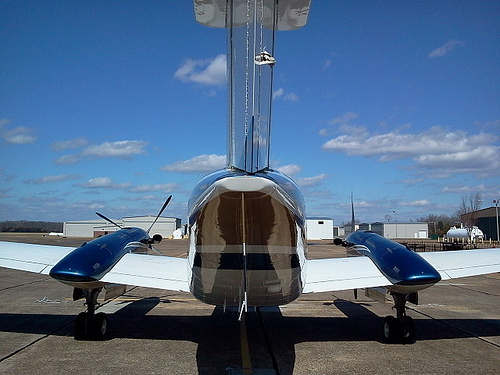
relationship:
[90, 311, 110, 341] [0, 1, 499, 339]
wheel on jet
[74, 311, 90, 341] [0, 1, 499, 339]
wheel on jet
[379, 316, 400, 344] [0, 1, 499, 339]
wheel on jet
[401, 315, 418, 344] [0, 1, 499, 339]
wheel on jet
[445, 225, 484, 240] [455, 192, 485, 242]
tank behind tree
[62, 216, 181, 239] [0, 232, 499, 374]
building on top of tarmac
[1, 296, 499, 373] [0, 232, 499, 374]
shadow on top of ground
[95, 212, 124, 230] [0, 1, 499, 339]
propeller on plane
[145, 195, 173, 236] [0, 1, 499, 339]
propeller on plane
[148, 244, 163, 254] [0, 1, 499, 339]
propeller on plane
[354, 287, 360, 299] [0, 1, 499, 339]
propeller on plane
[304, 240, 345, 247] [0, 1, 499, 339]
propeller on plane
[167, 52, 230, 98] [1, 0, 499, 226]
cloud in sky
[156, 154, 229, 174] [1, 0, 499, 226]
cloud in sky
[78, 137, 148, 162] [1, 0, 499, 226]
cloud in sky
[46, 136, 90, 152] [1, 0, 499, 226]
cloud in sky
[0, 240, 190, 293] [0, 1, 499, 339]
wing of plane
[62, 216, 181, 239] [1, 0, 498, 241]
building in background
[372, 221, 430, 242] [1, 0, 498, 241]
building in background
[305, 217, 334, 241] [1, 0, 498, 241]
building in background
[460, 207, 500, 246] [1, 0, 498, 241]
building in background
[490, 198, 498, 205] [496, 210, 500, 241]
street light on top of pole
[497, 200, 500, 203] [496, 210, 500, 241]
street light on top of pole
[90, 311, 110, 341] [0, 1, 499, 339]
wheel of jet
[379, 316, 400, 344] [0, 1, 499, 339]
wheel of jet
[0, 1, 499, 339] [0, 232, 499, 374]
jet on top of tarmac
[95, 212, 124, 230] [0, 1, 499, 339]
propeller on jet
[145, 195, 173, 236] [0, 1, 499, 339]
propeller on jet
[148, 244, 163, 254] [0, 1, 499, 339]
propeller on jet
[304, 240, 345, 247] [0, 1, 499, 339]
propeller on jet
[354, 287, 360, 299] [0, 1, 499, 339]
propeller on jet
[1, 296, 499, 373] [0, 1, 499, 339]
shadow of jet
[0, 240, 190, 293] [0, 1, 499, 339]
wing on jet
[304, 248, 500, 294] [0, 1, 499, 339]
wing on jet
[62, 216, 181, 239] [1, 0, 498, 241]
building in distance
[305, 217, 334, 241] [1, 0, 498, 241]
building in distance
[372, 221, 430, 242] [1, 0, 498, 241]
building in distance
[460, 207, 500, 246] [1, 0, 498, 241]
building in distance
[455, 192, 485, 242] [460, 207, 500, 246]
tree near building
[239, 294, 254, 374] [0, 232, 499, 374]
line on top of ground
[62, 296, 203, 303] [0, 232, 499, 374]
line on top of ground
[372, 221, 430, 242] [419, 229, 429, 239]
building has door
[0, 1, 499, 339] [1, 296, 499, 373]
jet has shadow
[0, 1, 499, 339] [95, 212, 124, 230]
jet has propeller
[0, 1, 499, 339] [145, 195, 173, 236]
jet has propeller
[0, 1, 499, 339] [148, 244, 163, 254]
jet has propeller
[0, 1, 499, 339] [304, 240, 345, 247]
jet has propeller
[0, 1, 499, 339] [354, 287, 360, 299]
jet has propeller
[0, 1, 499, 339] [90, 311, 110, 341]
jet has wheel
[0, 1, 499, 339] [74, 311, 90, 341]
jet has wheel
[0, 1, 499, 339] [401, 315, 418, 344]
jet has wheel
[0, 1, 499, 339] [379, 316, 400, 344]
jet has wheel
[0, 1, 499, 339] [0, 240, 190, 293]
jet has wing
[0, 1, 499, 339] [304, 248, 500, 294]
jet has wing